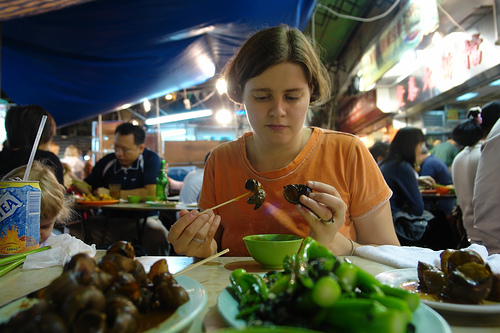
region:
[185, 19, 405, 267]
Woman wearing an orange shirt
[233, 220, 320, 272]
The bowl is green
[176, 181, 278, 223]
Meat on a stick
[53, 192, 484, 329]
Food on white plates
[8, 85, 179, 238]
The people are sitting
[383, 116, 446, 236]
Women wearing a blue shirt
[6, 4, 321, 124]
Blue tarp over the people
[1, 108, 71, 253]
Can with a clear straw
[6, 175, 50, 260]
The can is blue and orange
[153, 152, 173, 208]
The clear bottle is green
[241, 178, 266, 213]
cooked snail on a skewer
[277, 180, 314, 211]
brown shell of a snail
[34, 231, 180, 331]
heaping dish of escargot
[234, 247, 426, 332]
bright green vegetables on a plate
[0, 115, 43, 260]
can of iced tea with straw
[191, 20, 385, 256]
woman in an orange shirt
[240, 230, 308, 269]
green bowl on the table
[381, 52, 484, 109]
a sign written in asian language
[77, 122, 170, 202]
Man in a dark blue and white shirt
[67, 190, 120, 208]
a red cafeteria tray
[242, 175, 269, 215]
dinner snail on a stick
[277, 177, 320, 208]
snail shell in left hand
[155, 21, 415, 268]
brown haired teen girl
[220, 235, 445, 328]
dark green asparagus spears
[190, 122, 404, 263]
ladies orange casual shirt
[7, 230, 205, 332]
large pile of escargot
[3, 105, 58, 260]
can of tea with straw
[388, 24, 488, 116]
silver and red asian style sign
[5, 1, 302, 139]
dark blue ceiling awning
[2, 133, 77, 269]
small blonde child with hat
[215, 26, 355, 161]
woman with short brown hair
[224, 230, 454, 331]
green vegetables on a plate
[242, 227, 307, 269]
small green bowl on table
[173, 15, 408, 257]
woman wearing orange shirt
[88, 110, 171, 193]
man wearing blue shirt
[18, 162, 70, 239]
small girl with blond hair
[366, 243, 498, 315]
white ceramic plate on table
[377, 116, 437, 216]
woman with black hair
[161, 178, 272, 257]
hand holding wooden skewer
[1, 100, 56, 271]
straw in a metal can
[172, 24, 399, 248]
woman eating with chop sticks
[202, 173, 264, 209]
chop sticks in the woman's hand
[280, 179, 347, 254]
woman's left hand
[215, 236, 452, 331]
green food item on the table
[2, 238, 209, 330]
brown food item on the table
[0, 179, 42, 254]
can of nestea drink on the table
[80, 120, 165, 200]
man sitting at a table and eating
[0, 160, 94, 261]
the head of a little girl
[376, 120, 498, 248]
people eating in the background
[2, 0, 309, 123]
blue canopy over the eating area